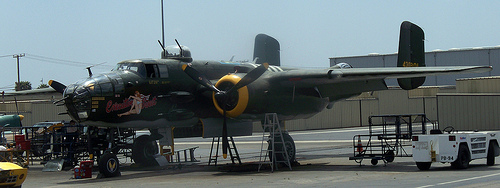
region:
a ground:
[297, 169, 342, 186]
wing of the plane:
[358, 66, 418, 83]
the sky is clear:
[293, 22, 343, 40]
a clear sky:
[201, 14, 288, 37]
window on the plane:
[146, 64, 160, 78]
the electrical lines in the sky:
[22, 50, 47, 63]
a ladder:
[263, 117, 291, 171]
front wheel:
[455, 147, 470, 166]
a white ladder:
[259, 118, 281, 165]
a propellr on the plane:
[186, 64, 273, 151]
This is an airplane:
[40, 9, 452, 152]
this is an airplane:
[16, 8, 433, 145]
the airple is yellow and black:
[54, 14, 339, 169]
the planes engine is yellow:
[192, 70, 277, 140]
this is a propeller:
[162, 44, 284, 161]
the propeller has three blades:
[182, 58, 311, 151]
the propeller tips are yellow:
[172, 59, 205, 85]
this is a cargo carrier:
[334, 120, 498, 177]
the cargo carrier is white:
[411, 148, 495, 168]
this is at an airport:
[20, 41, 442, 186]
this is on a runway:
[9, 45, 383, 187]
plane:
[69, 22, 454, 144]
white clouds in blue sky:
[39, 18, 66, 36]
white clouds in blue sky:
[119, 24, 159, 56]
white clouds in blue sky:
[193, 18, 233, 35]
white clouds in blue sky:
[307, 22, 339, 44]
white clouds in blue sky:
[332, 0, 373, 40]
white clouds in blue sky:
[437, 13, 498, 45]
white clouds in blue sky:
[112, 17, 139, 37]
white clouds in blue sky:
[9, 17, 53, 34]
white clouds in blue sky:
[77, 19, 114, 42]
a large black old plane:
[83, 26, 447, 158]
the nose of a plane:
[45, 71, 152, 131]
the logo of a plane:
[105, 83, 155, 117]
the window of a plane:
[110, 47, 162, 83]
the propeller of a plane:
[178, 55, 265, 134]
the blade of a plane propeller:
[167, 53, 210, 93]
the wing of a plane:
[280, 50, 479, 107]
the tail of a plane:
[380, 24, 435, 73]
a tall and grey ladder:
[255, 83, 301, 175]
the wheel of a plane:
[248, 131, 298, 171]